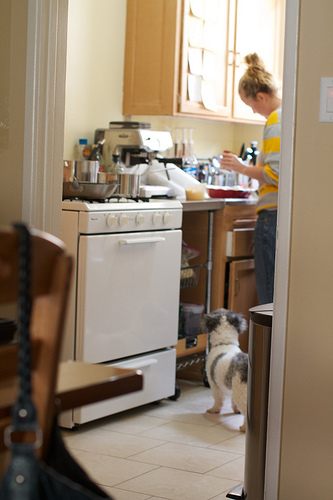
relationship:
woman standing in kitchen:
[220, 52, 281, 306] [57, 1, 271, 498]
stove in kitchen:
[61, 198, 184, 428] [57, 1, 271, 498]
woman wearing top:
[220, 52, 281, 306] [255, 108, 282, 215]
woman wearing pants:
[220, 52, 281, 306] [253, 210, 275, 307]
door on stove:
[72, 230, 181, 369] [61, 198, 184, 428]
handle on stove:
[119, 235, 168, 246] [61, 198, 184, 428]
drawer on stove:
[72, 346, 177, 428] [61, 198, 184, 428]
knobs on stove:
[106, 209, 172, 231] [61, 198, 184, 428]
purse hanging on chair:
[5, 220, 114, 499] [0, 223, 75, 466]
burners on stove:
[64, 194, 152, 206] [61, 198, 184, 428]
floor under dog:
[61, 374, 247, 499] [202, 303, 249, 435]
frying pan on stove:
[64, 176, 121, 200] [61, 198, 184, 428]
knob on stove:
[135, 212, 149, 228] [61, 198, 184, 428]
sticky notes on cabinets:
[185, 1, 226, 115] [122, 0, 284, 128]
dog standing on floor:
[202, 303, 249, 435] [61, 374, 247, 499]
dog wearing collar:
[202, 303, 249, 435] [208, 338, 241, 350]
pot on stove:
[96, 168, 143, 200] [61, 198, 184, 428]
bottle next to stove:
[74, 137, 90, 161] [61, 198, 184, 428]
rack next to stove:
[176, 196, 223, 401] [61, 198, 184, 428]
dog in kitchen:
[202, 303, 249, 435] [57, 1, 271, 498]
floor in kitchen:
[61, 374, 247, 499] [57, 1, 271, 498]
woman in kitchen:
[220, 52, 281, 306] [57, 1, 271, 498]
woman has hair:
[220, 52, 281, 306] [235, 49, 284, 98]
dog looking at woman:
[202, 303, 249, 435] [220, 52, 281, 306]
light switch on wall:
[318, 77, 333, 120] [263, 0, 332, 499]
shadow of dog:
[160, 408, 246, 446] [202, 303, 249, 435]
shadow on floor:
[160, 408, 246, 446] [61, 374, 247, 499]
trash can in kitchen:
[226, 301, 278, 499] [57, 1, 271, 498]